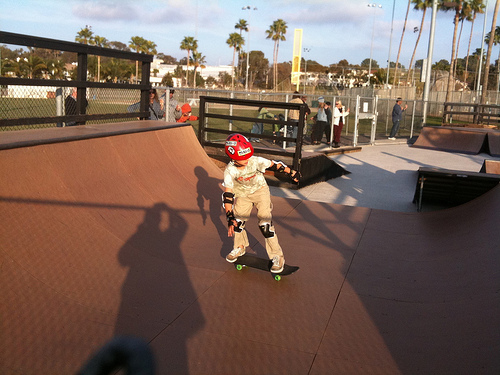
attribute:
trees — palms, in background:
[85, 24, 494, 83]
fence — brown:
[4, 31, 164, 125]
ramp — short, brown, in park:
[7, 97, 204, 266]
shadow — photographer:
[102, 155, 190, 363]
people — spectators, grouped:
[135, 98, 375, 144]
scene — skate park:
[6, 4, 481, 372]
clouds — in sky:
[76, 1, 302, 28]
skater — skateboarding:
[191, 136, 295, 302]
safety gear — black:
[217, 166, 277, 241]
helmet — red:
[212, 117, 244, 180]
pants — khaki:
[235, 176, 294, 261]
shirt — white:
[223, 152, 290, 207]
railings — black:
[1, 55, 142, 125]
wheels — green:
[216, 262, 280, 286]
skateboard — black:
[241, 241, 296, 282]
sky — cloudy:
[17, 5, 434, 41]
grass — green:
[182, 107, 318, 131]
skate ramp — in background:
[400, 71, 498, 177]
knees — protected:
[213, 210, 270, 250]